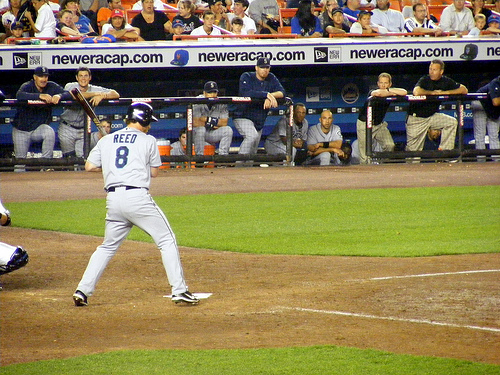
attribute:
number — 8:
[114, 142, 131, 169]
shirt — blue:
[239, 71, 283, 119]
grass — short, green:
[289, 201, 478, 243]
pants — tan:
[6, 125, 89, 166]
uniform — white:
[55, 132, 205, 319]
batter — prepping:
[67, 83, 204, 308]